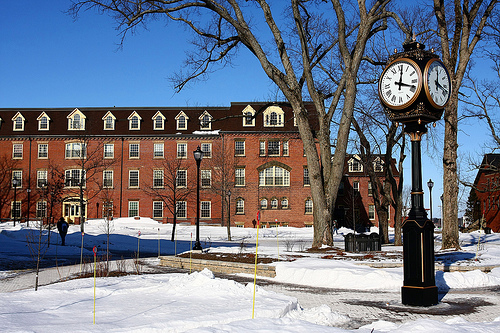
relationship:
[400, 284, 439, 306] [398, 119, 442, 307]
base of pole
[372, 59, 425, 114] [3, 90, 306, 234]
clock in front of building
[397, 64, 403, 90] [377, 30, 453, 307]
black hand on clock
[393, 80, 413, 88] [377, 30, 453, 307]
black hand on clock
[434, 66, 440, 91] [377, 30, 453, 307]
black hand on clock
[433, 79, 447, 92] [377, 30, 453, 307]
black hand on clock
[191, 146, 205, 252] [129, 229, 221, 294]
street light beside sidewalk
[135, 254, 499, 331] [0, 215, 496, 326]
sidewalk covered in snow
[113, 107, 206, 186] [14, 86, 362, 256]
windows on side of building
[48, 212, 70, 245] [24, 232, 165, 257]
person walking down sidewalk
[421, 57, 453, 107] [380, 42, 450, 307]
clock on tower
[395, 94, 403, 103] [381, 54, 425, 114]
numeral on clock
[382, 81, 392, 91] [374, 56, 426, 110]
numeral on clock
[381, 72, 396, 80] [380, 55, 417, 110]
roman numeral on clock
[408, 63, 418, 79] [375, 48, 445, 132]
numeral on clock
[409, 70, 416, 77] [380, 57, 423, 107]
numeral on clock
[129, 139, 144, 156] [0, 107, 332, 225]
window on building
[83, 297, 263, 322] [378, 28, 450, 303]
shadow of pole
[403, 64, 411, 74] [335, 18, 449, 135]
roman numeral on clock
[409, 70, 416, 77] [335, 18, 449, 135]
numeral on clock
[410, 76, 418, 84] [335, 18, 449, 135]
roman numeral on clock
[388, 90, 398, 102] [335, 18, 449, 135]
roman numeral on clock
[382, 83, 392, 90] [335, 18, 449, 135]
numeral on clock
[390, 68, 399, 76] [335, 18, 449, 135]
roman numeral on clock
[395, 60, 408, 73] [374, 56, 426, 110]
roman numeral on clock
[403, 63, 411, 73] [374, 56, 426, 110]
roman numeral on clock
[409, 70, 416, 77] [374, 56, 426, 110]
numeral on clock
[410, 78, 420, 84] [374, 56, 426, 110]
roman numeral on clock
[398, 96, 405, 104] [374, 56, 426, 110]
numeral on clock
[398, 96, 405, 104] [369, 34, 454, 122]
numeral on clock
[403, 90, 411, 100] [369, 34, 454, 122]
roman numeral on clock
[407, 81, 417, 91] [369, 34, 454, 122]
roman numeral on clock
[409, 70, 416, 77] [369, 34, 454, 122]
numeral on clock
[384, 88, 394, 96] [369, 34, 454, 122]
roman numeral on clock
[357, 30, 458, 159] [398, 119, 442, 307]
clock on pole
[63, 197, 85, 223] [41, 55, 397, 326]
doorway on building